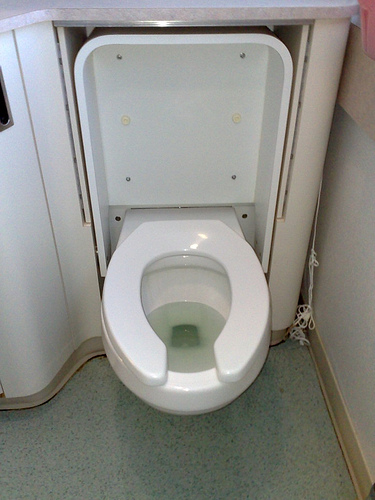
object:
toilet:
[97, 206, 271, 416]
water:
[145, 300, 225, 372]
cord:
[285, 177, 324, 346]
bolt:
[239, 53, 246, 59]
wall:
[17, 14, 355, 361]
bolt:
[115, 53, 124, 63]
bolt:
[230, 175, 238, 182]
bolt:
[124, 176, 132, 182]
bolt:
[242, 212, 248, 221]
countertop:
[1, 2, 361, 33]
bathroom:
[1, 1, 375, 499]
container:
[358, 2, 374, 61]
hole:
[2, 71, 16, 135]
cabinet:
[3, 27, 75, 404]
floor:
[1, 329, 359, 500]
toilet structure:
[72, 27, 297, 282]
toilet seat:
[101, 219, 265, 384]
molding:
[0, 295, 375, 499]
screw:
[231, 112, 243, 125]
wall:
[295, 98, 374, 483]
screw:
[120, 115, 131, 125]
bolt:
[114, 214, 121, 222]